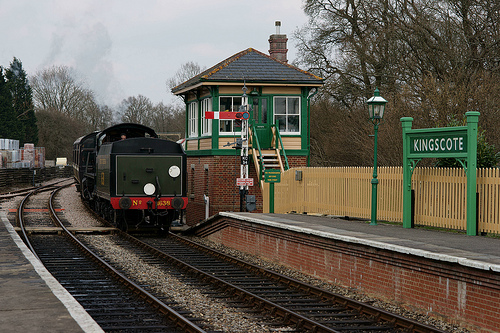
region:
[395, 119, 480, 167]
a green sign with white letters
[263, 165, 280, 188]
a green sign with yellow letters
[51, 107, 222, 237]
a black train on tracks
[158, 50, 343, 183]
a green and tan building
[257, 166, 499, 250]
a tan picket fence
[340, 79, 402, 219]
a green light pole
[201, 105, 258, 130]
a red board with white strip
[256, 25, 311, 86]
a chimney on the building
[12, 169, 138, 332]
empty track next to train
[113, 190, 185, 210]
yellow letters and numbers on train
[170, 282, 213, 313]
gray rocks on tracks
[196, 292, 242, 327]
gray rocks on tracks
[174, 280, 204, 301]
gray rocks on tracks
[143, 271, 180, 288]
gray rocks on tracks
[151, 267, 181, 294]
gray rocks on tracks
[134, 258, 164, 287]
gray rocks on tracks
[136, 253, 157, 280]
gray rocks on tracks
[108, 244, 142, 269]
gray rocks on tracks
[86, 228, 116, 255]
gray rocks on tracks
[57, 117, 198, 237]
This is a train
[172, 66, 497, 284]
This is a train stop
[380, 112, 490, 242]
This is a train stop sign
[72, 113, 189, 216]
The train is black and red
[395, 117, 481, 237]
The sign is green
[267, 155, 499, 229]
The fence is tan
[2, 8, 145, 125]
There are clouds in the background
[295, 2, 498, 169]
The trees are dying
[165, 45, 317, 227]
There is a small building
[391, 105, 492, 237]
small green sign that says Kingscote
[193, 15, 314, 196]
small cube shaped train station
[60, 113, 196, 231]
rear end of train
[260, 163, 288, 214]
small green sign with blurry letters, unable to read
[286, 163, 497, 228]
tan colored fencing alongside tracks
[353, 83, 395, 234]
green trimmed street light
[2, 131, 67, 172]
stacks of crates or boxes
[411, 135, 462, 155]
Kingscote on a sign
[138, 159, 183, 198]
two white circles on the back of a train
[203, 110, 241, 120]
a red and white wooden panel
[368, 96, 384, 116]
glass on a lamp post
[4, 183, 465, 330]
black iron railroad tracks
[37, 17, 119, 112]
smoke rising through the air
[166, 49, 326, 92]
the shingles on top of a roof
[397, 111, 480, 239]
a green metal sign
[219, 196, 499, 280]
a gray concrete platform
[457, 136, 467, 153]
A letter on a sign.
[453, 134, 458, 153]
A letter on a sign.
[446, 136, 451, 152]
A letter on a sign.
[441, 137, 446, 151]
A letter on a sign.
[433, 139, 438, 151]
A letter on a sign.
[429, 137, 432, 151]
A letter on a sign.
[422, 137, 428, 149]
A letter on a sign.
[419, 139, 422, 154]
A letter on a sign.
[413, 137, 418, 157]
A letter on a sign.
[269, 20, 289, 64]
chimney on top of train station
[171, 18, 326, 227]
green train station by tracks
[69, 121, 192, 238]
train on railroad tracks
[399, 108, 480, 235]
green sign next to tracks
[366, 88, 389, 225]
green light fixture next to tracks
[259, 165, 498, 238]
dark yellow fence next to tracks